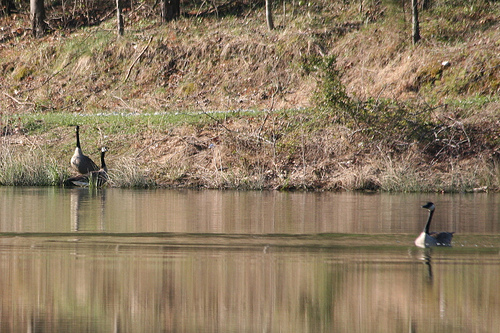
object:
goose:
[69, 124, 100, 175]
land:
[1, 0, 500, 193]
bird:
[413, 201, 455, 249]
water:
[0, 184, 500, 333]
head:
[420, 201, 436, 211]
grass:
[0, 0, 500, 195]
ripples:
[0, 185, 500, 333]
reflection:
[0, 183, 500, 333]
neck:
[73, 131, 83, 155]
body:
[414, 212, 455, 249]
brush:
[0, 149, 70, 188]